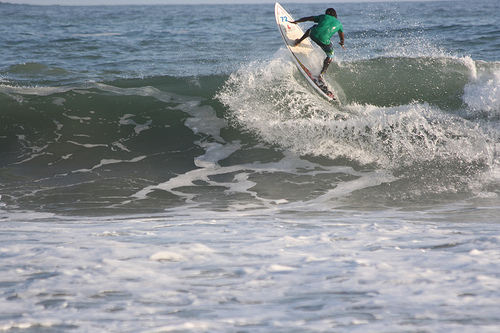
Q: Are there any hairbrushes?
A: No, there are no hairbrushes.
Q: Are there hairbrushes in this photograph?
A: No, there are no hairbrushes.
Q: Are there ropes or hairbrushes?
A: No, there are no hairbrushes or ropes.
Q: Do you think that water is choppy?
A: Yes, the water is choppy.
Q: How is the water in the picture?
A: The water is choppy.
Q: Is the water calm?
A: No, the water is choppy.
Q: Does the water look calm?
A: No, the water is choppy.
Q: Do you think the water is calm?
A: No, the water is choppy.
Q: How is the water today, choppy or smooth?
A: The water is choppy.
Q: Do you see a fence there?
A: No, there are no fences.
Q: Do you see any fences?
A: No, there are no fences.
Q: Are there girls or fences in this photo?
A: No, there are no fences or girls.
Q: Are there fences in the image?
A: No, there are no fences.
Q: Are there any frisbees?
A: No, there are no frisbees.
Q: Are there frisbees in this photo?
A: No, there are no frisbees.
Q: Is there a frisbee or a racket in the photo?
A: No, there are no frisbees or rackets.